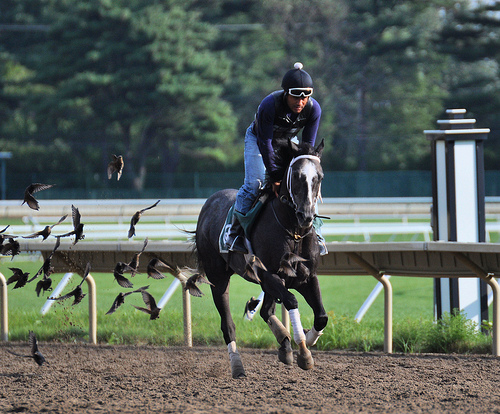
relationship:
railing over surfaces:
[1, 234, 498, 349] [339, 314, 379, 344]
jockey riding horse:
[197, 42, 354, 272] [191, 139, 330, 379]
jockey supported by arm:
[197, 42, 354, 272] [255, 95, 282, 178]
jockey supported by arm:
[197, 42, 354, 272] [301, 101, 319, 154]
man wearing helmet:
[204, 55, 370, 322] [239, 55, 340, 121]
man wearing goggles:
[204, 55, 370, 322] [284, 86, 318, 99]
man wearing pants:
[204, 55, 370, 322] [227, 112, 279, 252]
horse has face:
[174, 157, 368, 387] [291, 159, 321, 228]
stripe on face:
[300, 159, 319, 206] [291, 159, 321, 228]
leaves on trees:
[0, 0, 498, 158] [3, 4, 498, 174]